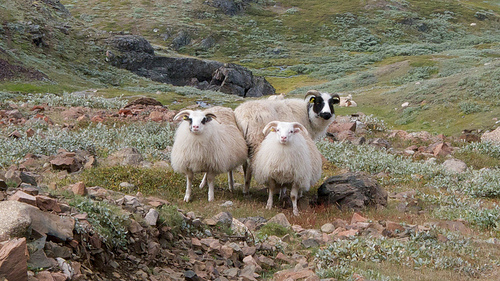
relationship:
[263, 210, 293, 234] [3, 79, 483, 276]
rock stuck in ground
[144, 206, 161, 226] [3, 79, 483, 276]
rock stuck in ground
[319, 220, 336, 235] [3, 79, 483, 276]
rock stuck in ground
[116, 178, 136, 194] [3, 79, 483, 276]
rock stuck in ground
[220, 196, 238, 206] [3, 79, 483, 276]
rock stuck in ground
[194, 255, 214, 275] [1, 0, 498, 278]
rock attached to ground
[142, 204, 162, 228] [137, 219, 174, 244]
rock stuck in ground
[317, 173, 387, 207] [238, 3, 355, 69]
rock on ground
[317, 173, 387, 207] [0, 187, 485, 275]
rock on ground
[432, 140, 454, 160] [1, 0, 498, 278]
rock stuck in ground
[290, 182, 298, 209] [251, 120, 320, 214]
sheep's leg of sheep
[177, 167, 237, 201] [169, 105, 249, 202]
sheep legs of goat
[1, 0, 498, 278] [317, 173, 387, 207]
ground full of rock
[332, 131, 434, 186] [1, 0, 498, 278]
bushes on ground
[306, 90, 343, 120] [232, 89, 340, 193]
head of goat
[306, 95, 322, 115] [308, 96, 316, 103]
ear of ear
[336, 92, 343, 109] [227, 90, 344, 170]
ear of sheep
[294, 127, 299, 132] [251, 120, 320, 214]
ear of sheep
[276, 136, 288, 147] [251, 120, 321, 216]
mouth of goat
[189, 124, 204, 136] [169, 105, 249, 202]
mouth of goat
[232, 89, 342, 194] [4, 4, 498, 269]
goat on hill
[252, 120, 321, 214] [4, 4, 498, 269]
goat on hill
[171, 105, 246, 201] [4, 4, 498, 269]
goat on hill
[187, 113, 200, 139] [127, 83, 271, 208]
nose on goat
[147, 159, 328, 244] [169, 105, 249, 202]
legs on a goat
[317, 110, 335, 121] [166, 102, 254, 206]
black nose on a goat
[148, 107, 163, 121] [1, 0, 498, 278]
rock in ground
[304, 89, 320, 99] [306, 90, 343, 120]
horn on head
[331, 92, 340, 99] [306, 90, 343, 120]
horn on head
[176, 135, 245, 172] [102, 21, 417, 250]
wool on sheep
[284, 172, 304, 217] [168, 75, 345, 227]
sheep's leg on sheep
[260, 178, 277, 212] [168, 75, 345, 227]
sheep's leg on sheep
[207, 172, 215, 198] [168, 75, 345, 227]
sheep legs on sheep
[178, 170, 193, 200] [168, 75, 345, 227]
sheep's leg on sheep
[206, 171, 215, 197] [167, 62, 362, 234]
legs on sheep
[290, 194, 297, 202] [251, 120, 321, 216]
spot on goat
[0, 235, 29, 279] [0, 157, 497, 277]
rock on ground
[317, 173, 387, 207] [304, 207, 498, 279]
rock in ground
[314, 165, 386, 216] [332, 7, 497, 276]
rock stuck in ground